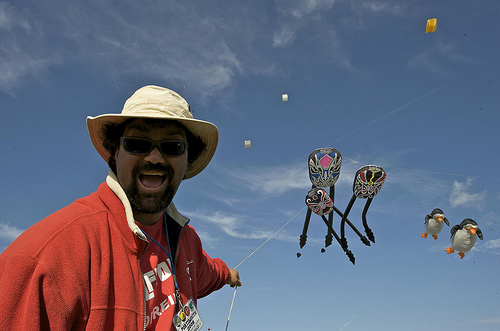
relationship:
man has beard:
[59, 84, 268, 277] [117, 164, 194, 215]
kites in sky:
[281, 116, 433, 282] [219, 16, 417, 117]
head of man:
[106, 89, 197, 214] [59, 84, 268, 277]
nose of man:
[151, 143, 177, 172] [59, 84, 268, 277]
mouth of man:
[143, 159, 174, 199] [59, 84, 268, 277]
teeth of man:
[138, 170, 170, 177] [59, 84, 268, 277]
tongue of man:
[143, 176, 168, 189] [59, 84, 268, 277]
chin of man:
[124, 197, 160, 217] [59, 84, 268, 277]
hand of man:
[219, 266, 246, 292] [59, 84, 268, 277]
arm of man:
[185, 239, 237, 291] [59, 84, 268, 277]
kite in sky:
[344, 160, 399, 215] [219, 16, 417, 117]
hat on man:
[99, 74, 235, 156] [59, 84, 268, 277]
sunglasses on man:
[123, 140, 202, 166] [59, 84, 268, 277]